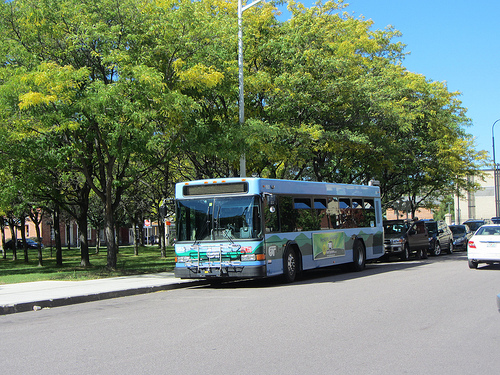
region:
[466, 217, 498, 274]
White vehicle on right side of street.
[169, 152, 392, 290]
A bus parked on street.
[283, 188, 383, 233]
Passenger windows on bus.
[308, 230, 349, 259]
An advertisement sign on side of bus.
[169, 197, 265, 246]
Front windshield on bus.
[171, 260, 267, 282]
Bumper on front of bus.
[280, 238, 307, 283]
Left front wheel of bus.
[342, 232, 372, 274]
Left back wheel of bus.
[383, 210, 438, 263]
Driver's side door on vehicle is open.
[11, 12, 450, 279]
A section of green trees.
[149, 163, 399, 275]
Bus parked near the sidewalk.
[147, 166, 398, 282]
The bus is mostly blue.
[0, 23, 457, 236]
Trees behind the bus.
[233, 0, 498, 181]
The sky is clear and blue.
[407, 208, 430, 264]
Somebody getting into their car.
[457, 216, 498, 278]
White sedan driving away.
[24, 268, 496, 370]
The road is asphalt.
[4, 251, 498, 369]
The road is gray.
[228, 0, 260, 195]
Light post right behind the bus.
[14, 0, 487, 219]
The leaves on the trees are green.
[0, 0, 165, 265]
Large trees with green leaves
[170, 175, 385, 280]
Parked blue bus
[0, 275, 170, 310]
Sidewalk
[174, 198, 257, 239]
Front windshield of a bus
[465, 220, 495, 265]
A white car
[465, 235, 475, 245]
Car tail light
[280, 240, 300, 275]
Wheels on a bus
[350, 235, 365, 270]
Wheels on a bus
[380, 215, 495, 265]
Multiple paralled parked cars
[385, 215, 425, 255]
Parked SUV with one of its front doors opened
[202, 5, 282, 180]
the post is silver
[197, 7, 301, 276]
the post is silver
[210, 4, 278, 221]
the post is silverthe post is silver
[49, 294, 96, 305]
edge on white side walk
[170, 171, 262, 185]
orange circles on top of bus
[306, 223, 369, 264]
green billboard on side of bus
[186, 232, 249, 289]
bike rack on front of bus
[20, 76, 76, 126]
cluster of yellow leaves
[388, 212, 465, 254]
cars parked at side of road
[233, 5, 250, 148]
tall lighting post on side walk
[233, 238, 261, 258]
pink sign on front of blue bus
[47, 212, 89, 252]
white trim on red house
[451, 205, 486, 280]
white car going down the street